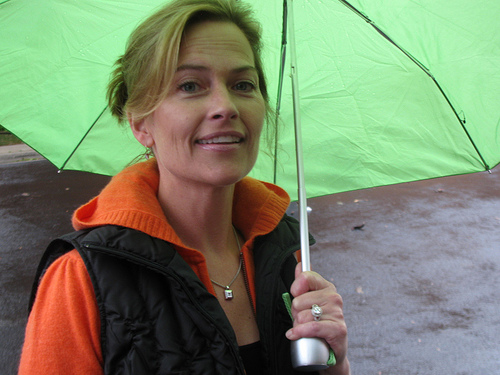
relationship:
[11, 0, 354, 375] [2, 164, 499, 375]
woman in street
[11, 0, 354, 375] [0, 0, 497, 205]
woman holds umbrella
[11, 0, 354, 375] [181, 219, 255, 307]
woman wears necklace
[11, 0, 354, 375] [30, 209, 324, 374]
woman wears vest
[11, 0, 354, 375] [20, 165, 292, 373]
woman wears sweater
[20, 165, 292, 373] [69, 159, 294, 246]
sweater has hood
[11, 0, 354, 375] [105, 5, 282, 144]
woman has hair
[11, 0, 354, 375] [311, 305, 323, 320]
woman has ring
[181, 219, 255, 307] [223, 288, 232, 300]
necklace has pendant